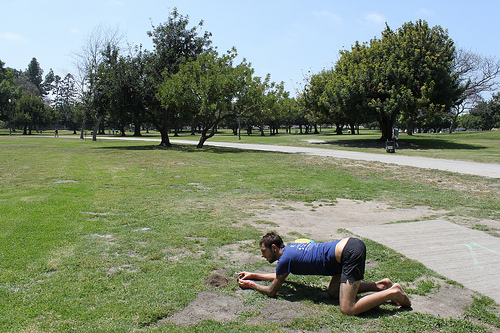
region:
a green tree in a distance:
[18, 88, 47, 135]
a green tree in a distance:
[0, 55, 17, 130]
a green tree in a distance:
[25, 54, 40, 89]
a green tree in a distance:
[40, 67, 58, 91]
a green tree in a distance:
[53, 71, 79, 131]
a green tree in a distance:
[71, 28, 116, 125]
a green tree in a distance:
[166, 51, 268, 157]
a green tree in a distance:
[125, 6, 207, 151]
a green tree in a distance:
[308, 16, 462, 149]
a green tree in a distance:
[253, 75, 301, 131]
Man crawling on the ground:
[223, 224, 438, 316]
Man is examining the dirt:
[242, 231, 294, 266]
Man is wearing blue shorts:
[330, 230, 370, 315]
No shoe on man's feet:
[340, 266, 440, 322]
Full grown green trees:
[66, 25, 256, 151]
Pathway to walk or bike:
[122, 145, 493, 175]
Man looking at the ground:
[226, 220, 427, 315]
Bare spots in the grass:
[135, 280, 270, 330]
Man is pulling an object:
[369, 120, 436, 167]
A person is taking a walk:
[42, 122, 69, 154]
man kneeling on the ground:
[229, 218, 421, 324]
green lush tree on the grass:
[313, 20, 470, 152]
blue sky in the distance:
[237, 15, 341, 55]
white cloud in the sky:
[359, 11, 391, 26]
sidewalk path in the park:
[331, 140, 496, 183]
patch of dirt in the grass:
[182, 290, 247, 325]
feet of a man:
[374, 276, 416, 311]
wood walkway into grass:
[367, 203, 498, 308]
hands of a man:
[223, 264, 258, 294]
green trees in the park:
[0, 12, 492, 152]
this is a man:
[226, 229, 413, 309]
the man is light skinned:
[344, 289, 350, 306]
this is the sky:
[256, 7, 305, 60]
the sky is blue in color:
[36, 10, 56, 37]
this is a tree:
[170, 62, 236, 143]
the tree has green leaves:
[174, 85, 189, 100]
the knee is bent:
[333, 300, 368, 317]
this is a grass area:
[16, 210, 74, 237]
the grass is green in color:
[18, 219, 39, 239]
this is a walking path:
[401, 152, 426, 168]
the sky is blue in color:
[254, 20, 313, 45]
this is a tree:
[366, 22, 430, 121]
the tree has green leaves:
[388, 57, 410, 75]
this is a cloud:
[370, 12, 382, 24]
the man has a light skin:
[364, 297, 371, 302]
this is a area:
[13, 200, 77, 254]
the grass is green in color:
[25, 211, 49, 236]